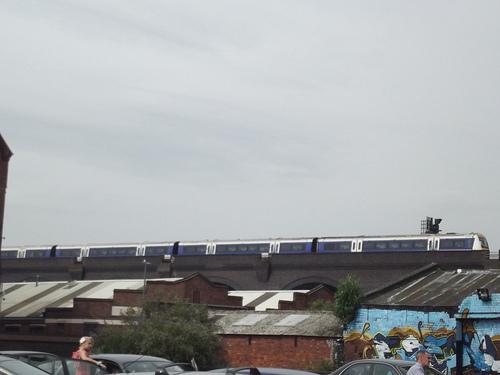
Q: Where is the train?
A: On bridge.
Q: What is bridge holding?
A: Train.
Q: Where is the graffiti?
A: On wall.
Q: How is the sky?
A: Cloudy.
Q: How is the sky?
A: Gray.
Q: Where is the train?
A: On rails.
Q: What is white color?
A: Train.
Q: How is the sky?
A: Overcast.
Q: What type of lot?
A: Parking.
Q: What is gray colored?
A: Clouds.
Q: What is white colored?
A: Clouds.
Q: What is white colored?
A: Train.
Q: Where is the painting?
A: On wall.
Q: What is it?
A: Train.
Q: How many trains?
A: 1.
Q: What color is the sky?
A: Gray.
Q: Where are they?
A: On the train.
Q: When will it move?
A: Now.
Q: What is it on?
A: Tracks.